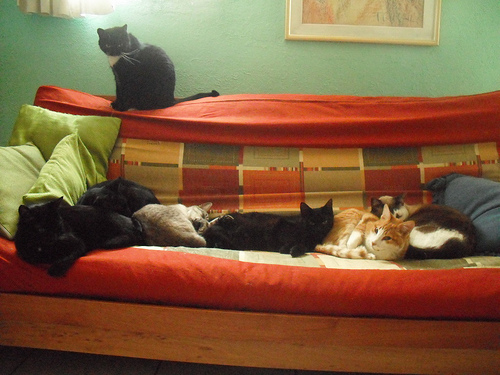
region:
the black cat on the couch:
[92, 23, 221, 112]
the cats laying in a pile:
[5, 168, 482, 277]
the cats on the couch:
[0, 23, 494, 278]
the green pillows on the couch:
[1, 91, 129, 176]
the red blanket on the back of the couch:
[223, 89, 494, 151]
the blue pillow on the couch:
[426, 171, 498, 211]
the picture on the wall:
[273, 0, 435, 53]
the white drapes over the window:
[15, 0, 80, 32]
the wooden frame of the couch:
[6, 295, 493, 374]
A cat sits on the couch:
[86, 18, 230, 119]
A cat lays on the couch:
[6, 189, 133, 268]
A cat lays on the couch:
[132, 194, 223, 261]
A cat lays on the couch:
[198, 196, 340, 279]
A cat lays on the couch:
[307, 198, 414, 280]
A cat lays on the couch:
[367, 191, 479, 265]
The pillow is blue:
[427, 151, 499, 258]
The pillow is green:
[0, 94, 126, 242]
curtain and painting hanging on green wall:
[1, 1, 492, 137]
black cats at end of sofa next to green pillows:
[0, 100, 160, 270]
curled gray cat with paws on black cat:
[135, 195, 330, 255]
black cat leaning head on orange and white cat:
[290, 200, 410, 255]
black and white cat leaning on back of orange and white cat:
[365, 186, 481, 256]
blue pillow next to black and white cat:
[410, 170, 492, 255]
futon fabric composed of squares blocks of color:
[105, 131, 495, 281]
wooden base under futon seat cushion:
[5, 290, 495, 370]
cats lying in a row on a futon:
[5, 155, 495, 277]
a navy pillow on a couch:
[432, 172, 498, 246]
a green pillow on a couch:
[12, 101, 122, 180]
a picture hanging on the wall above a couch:
[281, 1, 444, 47]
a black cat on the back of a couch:
[94, 22, 221, 109]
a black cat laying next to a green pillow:
[15, 196, 141, 276]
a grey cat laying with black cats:
[129, 200, 235, 249]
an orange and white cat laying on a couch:
[320, 202, 412, 261]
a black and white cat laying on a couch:
[368, 193, 478, 257]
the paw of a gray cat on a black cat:
[211, 211, 235, 230]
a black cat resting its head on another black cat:
[81, 172, 159, 217]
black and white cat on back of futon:
[93, 23, 218, 113]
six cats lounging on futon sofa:
[17, 178, 484, 265]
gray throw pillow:
[426, 168, 498, 255]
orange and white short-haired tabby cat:
[315, 207, 411, 261]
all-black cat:
[193, 199, 332, 256]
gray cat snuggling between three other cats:
[129, 199, 231, 248]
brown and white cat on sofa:
[366, 193, 480, 258]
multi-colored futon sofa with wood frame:
[0, 86, 499, 373]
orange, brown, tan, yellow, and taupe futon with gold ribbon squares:
[0, 86, 499, 317]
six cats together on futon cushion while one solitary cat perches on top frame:
[3, 22, 498, 374]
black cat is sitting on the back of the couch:
[96, 23, 228, 115]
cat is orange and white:
[318, 195, 417, 265]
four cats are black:
[11, 25, 336, 270]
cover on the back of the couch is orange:
[31, 85, 498, 150]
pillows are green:
[1, 95, 118, 240]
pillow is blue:
[436, 168, 499, 251]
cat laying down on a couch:
[200, 185, 344, 242]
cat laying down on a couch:
[335, 199, 395, 274]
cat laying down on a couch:
[386, 192, 464, 261]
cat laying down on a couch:
[123, 185, 200, 246]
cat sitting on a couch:
[86, 14, 200, 151]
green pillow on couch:
[22, 106, 106, 200]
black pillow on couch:
[432, 159, 499, 241]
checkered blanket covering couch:
[121, 121, 487, 291]